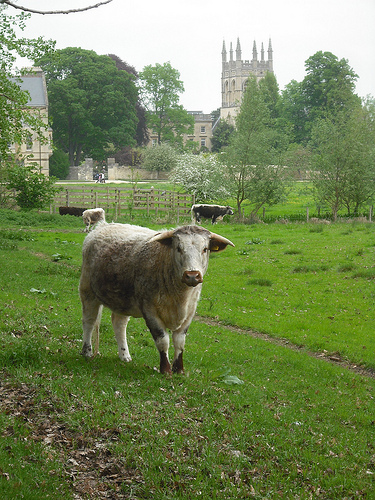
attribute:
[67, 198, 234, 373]
cow — white, brown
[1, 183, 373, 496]
pasture — grassy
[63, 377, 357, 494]
pasture — grassy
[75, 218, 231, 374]
cow — grassy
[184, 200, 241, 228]
cow — black, white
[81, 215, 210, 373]
cow — white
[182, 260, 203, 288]
nose — brown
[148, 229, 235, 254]
horns — white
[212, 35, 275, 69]
spires — top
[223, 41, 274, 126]
tower —  bell 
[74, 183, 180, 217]
fence — stone 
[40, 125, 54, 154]
window — bowed 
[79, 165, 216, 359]
cow — white cow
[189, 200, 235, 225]
cow — brown, black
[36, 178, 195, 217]
fence — wood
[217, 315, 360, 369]
path — dirt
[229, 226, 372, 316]
grass — green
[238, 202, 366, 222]
fence — wood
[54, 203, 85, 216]
cows — brown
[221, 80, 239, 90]
openings — arched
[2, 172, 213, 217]
fencing — wooden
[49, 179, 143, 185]
walkway — far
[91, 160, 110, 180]
entry — gated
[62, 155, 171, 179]
wall — stone